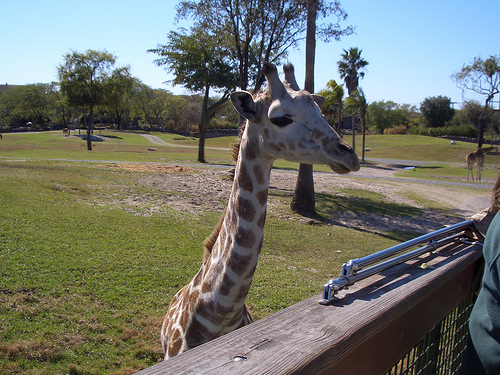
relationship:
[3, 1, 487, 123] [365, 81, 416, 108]
sky has clouds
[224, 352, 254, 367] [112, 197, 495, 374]
nail in wood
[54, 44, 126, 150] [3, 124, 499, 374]
tree in pen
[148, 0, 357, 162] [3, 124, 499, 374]
tree in pen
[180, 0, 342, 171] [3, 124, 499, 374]
tree in pen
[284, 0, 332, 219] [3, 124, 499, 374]
tree in pen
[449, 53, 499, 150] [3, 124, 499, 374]
tree in pen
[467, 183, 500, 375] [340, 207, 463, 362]
jumper standing by fence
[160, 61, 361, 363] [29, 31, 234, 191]
animal in distance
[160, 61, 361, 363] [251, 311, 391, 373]
animal in front of fence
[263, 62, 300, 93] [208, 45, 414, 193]
head horns on head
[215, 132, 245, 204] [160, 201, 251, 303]
hair on back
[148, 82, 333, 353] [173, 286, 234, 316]
skin has patterns